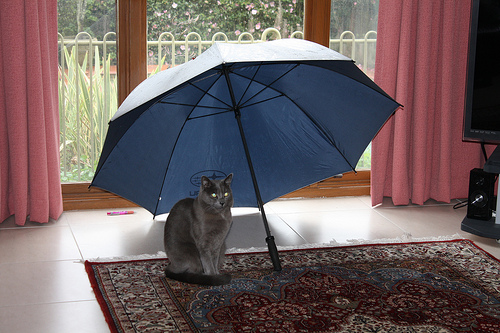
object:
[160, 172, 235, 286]
cat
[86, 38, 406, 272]
umbrella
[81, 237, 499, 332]
rug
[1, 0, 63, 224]
curtains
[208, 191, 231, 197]
eyes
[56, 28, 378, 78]
fence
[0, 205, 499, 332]
floor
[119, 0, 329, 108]
door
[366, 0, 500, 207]
curtain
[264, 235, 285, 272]
handle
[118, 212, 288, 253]
shadow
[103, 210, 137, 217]
marker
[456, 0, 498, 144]
television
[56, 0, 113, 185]
window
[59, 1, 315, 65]
bush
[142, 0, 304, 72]
window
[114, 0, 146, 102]
wood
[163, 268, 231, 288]
tail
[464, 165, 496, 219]
speakers